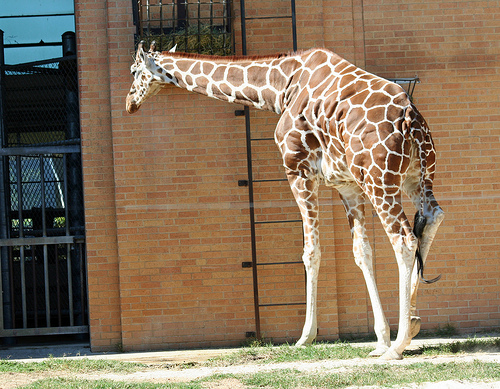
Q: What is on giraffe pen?
A: Metal barrier.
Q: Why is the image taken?
A: Remembrance.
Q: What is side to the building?
A: Bricks.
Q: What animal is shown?
A: Giraffe.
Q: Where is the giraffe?
A: In an enclosure.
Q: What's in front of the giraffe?
A: A building.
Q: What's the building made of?
A: Bricks.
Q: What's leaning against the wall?
A: A ladder.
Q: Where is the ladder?
A: Leaning against a wall.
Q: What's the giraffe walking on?
A: Grass.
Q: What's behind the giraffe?
A: Its tail.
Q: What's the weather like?
A: Sunny.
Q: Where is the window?
A: Next to the ladder.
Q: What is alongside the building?
A: A fence.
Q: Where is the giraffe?
A: In a pen.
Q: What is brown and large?
A: Giraffe.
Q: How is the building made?
A: With bricks.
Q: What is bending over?
A: Neck of giraffe.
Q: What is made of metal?
A: Ladder.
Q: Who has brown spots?
A: Giraffe.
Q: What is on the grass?
A: Giraffe.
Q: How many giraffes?
A: 1.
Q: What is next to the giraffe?
A: Wall.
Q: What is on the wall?
A: Ladder.